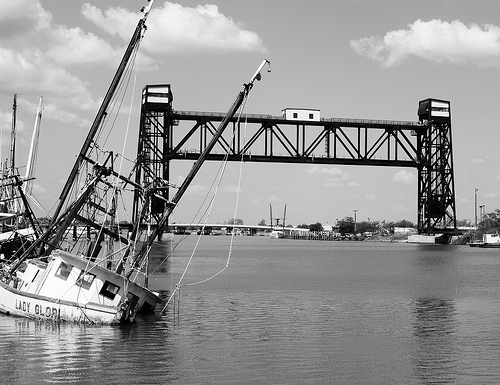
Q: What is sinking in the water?
A: The fishing boat.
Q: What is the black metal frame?
A: A tower.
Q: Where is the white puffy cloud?
A: In the sky.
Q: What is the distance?
A: Long bridge.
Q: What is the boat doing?
A: Sinking.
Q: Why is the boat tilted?
A: It's sinking.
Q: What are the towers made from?
A: Metal.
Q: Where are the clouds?
A: In the sky.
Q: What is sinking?
A: Ship.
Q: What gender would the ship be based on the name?
A: Female.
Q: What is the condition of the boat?
A: Wrecked.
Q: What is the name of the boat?
A: Lady Glory.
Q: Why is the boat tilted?
A: Sinking.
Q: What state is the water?
A: Tranquil.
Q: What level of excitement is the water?
A: Sedated.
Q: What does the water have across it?
A: Ripples.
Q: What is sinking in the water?
A: A boat.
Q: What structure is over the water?
A: Bridge.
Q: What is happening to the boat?
A: Starting to sink.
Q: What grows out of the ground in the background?
A: Trees.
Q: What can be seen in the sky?
A: Clouds.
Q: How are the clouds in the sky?
A: Light and fluffy.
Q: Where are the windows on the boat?
A: On the side.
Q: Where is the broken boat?
A: In the front.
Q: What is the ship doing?
A: Sinking.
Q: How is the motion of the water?
A: Still.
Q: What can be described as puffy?
A: Clouds.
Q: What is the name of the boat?
A: Lady Glory.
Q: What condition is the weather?
A: Calm.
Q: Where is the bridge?
A: Over a canal.